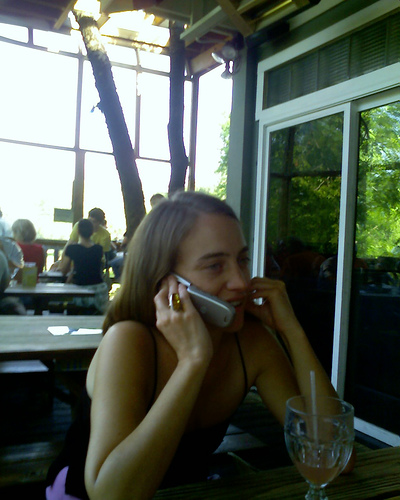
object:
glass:
[284, 393, 355, 500]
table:
[196, 447, 400, 500]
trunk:
[165, 21, 190, 199]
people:
[59, 208, 117, 269]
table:
[4, 282, 108, 297]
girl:
[64, 188, 345, 500]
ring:
[168, 292, 183, 313]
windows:
[251, 5, 399, 118]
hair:
[101, 191, 240, 336]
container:
[21, 261, 38, 287]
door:
[241, 0, 400, 449]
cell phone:
[169, 271, 236, 328]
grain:
[341, 475, 396, 494]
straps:
[147, 328, 160, 398]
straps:
[234, 335, 250, 391]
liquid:
[297, 464, 340, 486]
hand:
[154, 274, 213, 362]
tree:
[69, 5, 148, 244]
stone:
[172, 293, 183, 313]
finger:
[167, 272, 178, 311]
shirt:
[64, 317, 248, 498]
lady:
[56, 219, 105, 306]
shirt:
[12, 241, 45, 276]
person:
[9, 218, 46, 284]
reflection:
[264, 103, 398, 260]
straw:
[310, 371, 320, 469]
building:
[0, 0, 400, 500]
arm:
[85, 325, 210, 497]